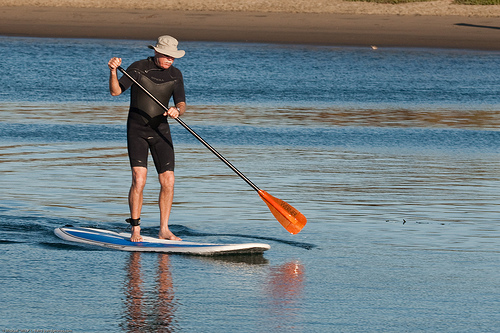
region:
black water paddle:
[107, 55, 314, 242]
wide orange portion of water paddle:
[248, 185, 328, 240]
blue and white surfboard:
[44, 214, 269, 263]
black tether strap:
[116, 214, 146, 233]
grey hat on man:
[142, 29, 189, 62]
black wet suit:
[118, 57, 196, 179]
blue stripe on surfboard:
[58, 221, 230, 261]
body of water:
[6, 30, 498, 323]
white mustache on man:
[160, 58, 175, 66]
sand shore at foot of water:
[4, 3, 499, 60]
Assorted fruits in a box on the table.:
[368, 181, 376, 323]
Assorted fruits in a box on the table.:
[29, 165, 67, 309]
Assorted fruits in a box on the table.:
[419, 138, 430, 183]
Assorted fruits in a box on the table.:
[116, 244, 156, 316]